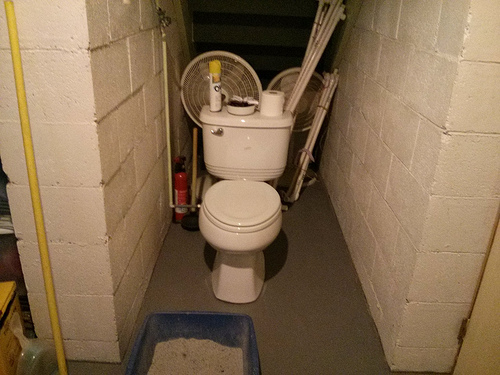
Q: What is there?
A: Toilet.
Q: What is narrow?
A: The space.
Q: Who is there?
A: No one.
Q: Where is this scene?
A: Bathroom.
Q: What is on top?
A: Toilet tissue.